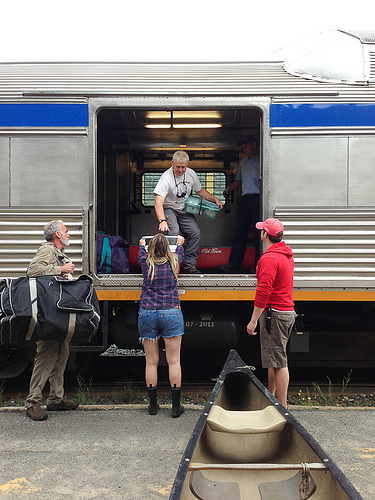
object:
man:
[23, 218, 76, 422]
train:
[0, 26, 375, 378]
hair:
[43, 219, 65, 242]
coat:
[253, 238, 295, 315]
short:
[257, 309, 296, 370]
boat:
[167, 345, 369, 500]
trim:
[141, 234, 178, 238]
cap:
[254, 214, 283, 237]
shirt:
[135, 240, 186, 312]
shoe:
[24, 400, 49, 423]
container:
[139, 233, 180, 253]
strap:
[171, 166, 187, 189]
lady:
[135, 230, 185, 420]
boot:
[168, 382, 185, 419]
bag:
[0, 244, 103, 348]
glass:
[176, 181, 188, 199]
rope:
[186, 459, 330, 472]